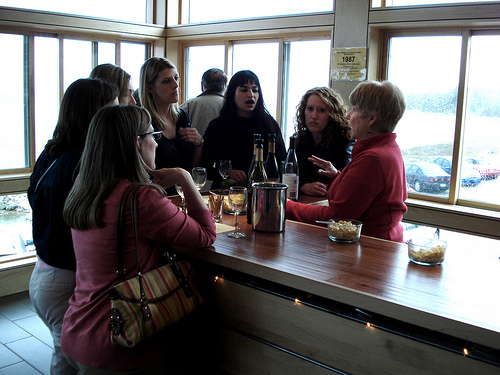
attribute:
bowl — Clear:
[403, 233, 450, 268]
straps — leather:
[128, 182, 203, 352]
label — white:
[279, 172, 301, 201]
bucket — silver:
[251, 180, 289, 237]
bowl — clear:
[319, 214, 364, 250]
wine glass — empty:
[228, 183, 247, 239]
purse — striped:
[99, 179, 192, 349]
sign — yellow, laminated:
[328, 44, 368, 84]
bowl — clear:
[222, 188, 249, 214]